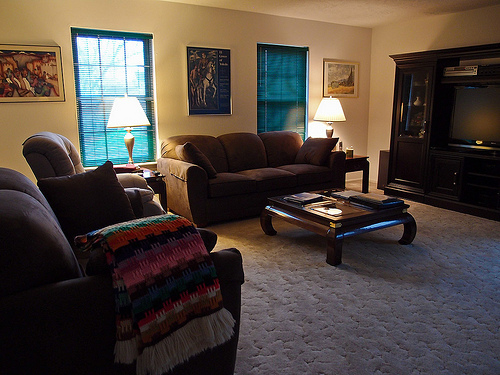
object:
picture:
[322, 57, 359, 98]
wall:
[309, 19, 372, 182]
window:
[70, 27, 161, 169]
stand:
[384, 51, 433, 206]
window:
[257, 42, 308, 143]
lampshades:
[106, 96, 346, 127]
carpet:
[195, 178, 498, 375]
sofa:
[0, 160, 245, 374]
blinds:
[71, 27, 156, 168]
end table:
[113, 167, 168, 214]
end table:
[330, 154, 369, 194]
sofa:
[157, 131, 347, 228]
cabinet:
[385, 43, 500, 223]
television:
[447, 85, 499, 150]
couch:
[156, 131, 346, 229]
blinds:
[257, 42, 307, 143]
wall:
[367, 5, 500, 188]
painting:
[0, 44, 65, 103]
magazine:
[283, 192, 325, 204]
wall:
[0, 0, 80, 186]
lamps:
[106, 96, 346, 169]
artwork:
[187, 46, 233, 116]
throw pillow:
[37, 160, 136, 237]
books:
[280, 190, 404, 211]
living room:
[0, 0, 500, 375]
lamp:
[313, 98, 347, 152]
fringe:
[114, 308, 237, 374]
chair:
[0, 160, 246, 375]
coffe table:
[259, 188, 417, 268]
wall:
[0, 0, 500, 184]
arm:
[53, 248, 245, 315]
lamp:
[106, 96, 151, 170]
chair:
[22, 130, 167, 220]